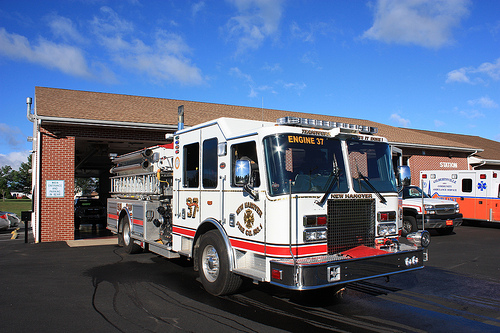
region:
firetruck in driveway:
[107, 118, 429, 297]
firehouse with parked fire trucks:
[26, 85, 496, 250]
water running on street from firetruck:
[83, 254, 499, 329]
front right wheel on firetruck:
[190, 216, 242, 295]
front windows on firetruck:
[261, 132, 401, 194]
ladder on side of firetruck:
[107, 174, 162, 196]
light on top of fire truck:
[279, 117, 372, 137]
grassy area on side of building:
[0, 190, 33, 240]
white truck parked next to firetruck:
[399, 185, 459, 236]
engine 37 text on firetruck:
[287, 134, 326, 144]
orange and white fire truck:
[104, 92, 440, 301]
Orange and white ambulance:
[415, 162, 498, 229]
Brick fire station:
[20, 74, 497, 269]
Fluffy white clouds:
[4, 30, 92, 76]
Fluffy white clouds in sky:
[0, 3, 498, 125]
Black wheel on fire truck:
[188, 228, 242, 303]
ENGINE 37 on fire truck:
[282, 128, 329, 149]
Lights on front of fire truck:
[304, 209, 406, 246]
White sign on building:
[45, 176, 70, 201]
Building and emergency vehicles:
[22, 55, 497, 289]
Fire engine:
[105, 105, 436, 310]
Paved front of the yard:
[7, 252, 142, 331]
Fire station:
[3, 33, 498, 318]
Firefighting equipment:
[106, 126, 175, 268]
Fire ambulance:
[418, 163, 496, 228]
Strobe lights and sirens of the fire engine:
[268, 107, 390, 139]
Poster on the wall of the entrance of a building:
[41, 164, 74, 224]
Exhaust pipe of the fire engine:
[170, 98, 190, 136]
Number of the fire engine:
[285, 128, 328, 151]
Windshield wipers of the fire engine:
[315, 146, 387, 206]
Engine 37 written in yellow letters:
[282, 127, 327, 146]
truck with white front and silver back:
[99, 116, 411, 280]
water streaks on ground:
[83, 246, 498, 330]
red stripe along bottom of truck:
[107, 202, 391, 272]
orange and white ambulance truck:
[420, 163, 498, 223]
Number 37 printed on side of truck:
[183, 196, 202, 223]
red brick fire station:
[37, 124, 479, 245]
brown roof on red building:
[34, 87, 476, 158]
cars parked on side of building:
[0, 197, 23, 235]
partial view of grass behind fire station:
[0, 194, 38, 207]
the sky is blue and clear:
[69, 14, 274, 88]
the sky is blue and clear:
[62, 6, 382, 173]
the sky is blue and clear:
[156, 0, 296, 111]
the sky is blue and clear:
[171, 26, 386, 120]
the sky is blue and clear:
[164, 37, 325, 91]